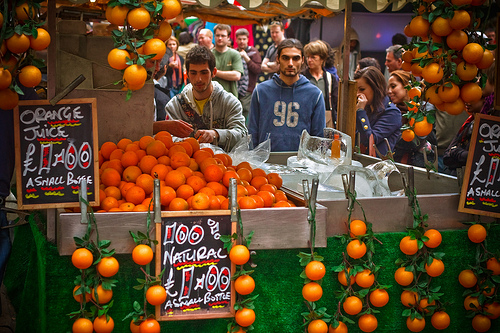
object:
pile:
[61, 129, 302, 215]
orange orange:
[165, 160, 212, 210]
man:
[163, 44, 250, 152]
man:
[209, 22, 246, 100]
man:
[232, 26, 263, 118]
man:
[259, 19, 289, 79]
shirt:
[245, 71, 328, 153]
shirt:
[163, 80, 249, 154]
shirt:
[209, 45, 246, 100]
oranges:
[157, 154, 171, 165]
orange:
[420, 64, 445, 84]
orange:
[398, 235, 419, 256]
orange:
[203, 164, 225, 184]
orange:
[198, 185, 216, 197]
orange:
[190, 193, 210, 211]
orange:
[238, 196, 257, 209]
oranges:
[145, 285, 168, 306]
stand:
[0, 145, 500, 333]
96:
[271, 100, 300, 128]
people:
[386, 69, 438, 168]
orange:
[348, 219, 369, 240]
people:
[245, 37, 328, 154]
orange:
[169, 151, 191, 169]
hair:
[303, 39, 329, 68]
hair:
[276, 37, 305, 65]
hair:
[185, 44, 217, 77]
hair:
[213, 23, 231, 37]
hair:
[267, 19, 285, 31]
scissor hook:
[300, 173, 322, 224]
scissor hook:
[341, 169, 358, 212]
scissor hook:
[399, 165, 417, 206]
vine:
[310, 221, 317, 253]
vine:
[348, 201, 355, 229]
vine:
[405, 187, 424, 226]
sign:
[153, 209, 239, 323]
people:
[354, 64, 404, 157]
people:
[301, 38, 338, 130]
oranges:
[185, 175, 205, 193]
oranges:
[256, 190, 277, 207]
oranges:
[119, 150, 139, 169]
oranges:
[146, 139, 167, 158]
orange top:
[330, 134, 341, 159]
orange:
[163, 169, 188, 190]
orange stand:
[0, 129, 500, 332]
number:
[272, 100, 288, 127]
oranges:
[100, 140, 120, 160]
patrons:
[164, 36, 186, 98]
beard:
[279, 67, 301, 77]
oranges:
[446, 9, 471, 31]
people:
[383, 42, 406, 72]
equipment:
[264, 126, 409, 200]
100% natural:
[160, 216, 228, 266]